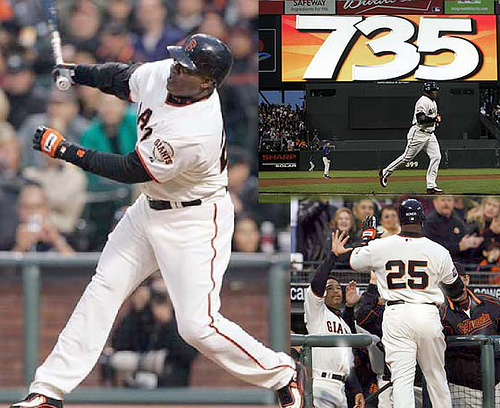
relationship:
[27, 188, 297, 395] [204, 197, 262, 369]
pants with stripe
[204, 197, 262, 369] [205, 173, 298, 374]
stripe on side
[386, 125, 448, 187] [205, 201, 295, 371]
pants with stripe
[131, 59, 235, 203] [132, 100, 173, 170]
shirt with black letters